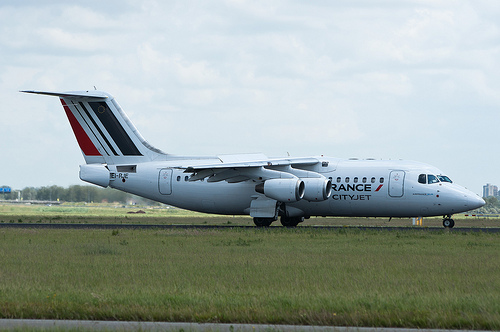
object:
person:
[430, 176, 437, 182]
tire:
[443, 219, 455, 228]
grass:
[0, 202, 500, 324]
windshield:
[436, 175, 452, 183]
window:
[362, 176, 367, 183]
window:
[337, 177, 342, 183]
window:
[344, 177, 349, 184]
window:
[185, 176, 189, 182]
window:
[345, 177, 350, 184]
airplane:
[16, 85, 488, 229]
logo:
[325, 176, 384, 201]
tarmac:
[0, 223, 497, 234]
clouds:
[235, 29, 353, 117]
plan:
[48, 90, 486, 227]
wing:
[168, 157, 321, 183]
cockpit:
[417, 173, 453, 185]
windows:
[176, 175, 182, 181]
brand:
[331, 184, 372, 201]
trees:
[67, 184, 83, 203]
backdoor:
[158, 167, 174, 195]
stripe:
[87, 101, 144, 155]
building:
[483, 183, 498, 198]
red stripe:
[56, 98, 102, 156]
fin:
[58, 90, 158, 163]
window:
[418, 173, 427, 184]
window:
[427, 174, 439, 184]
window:
[436, 175, 452, 183]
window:
[327, 176, 332, 182]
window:
[371, 177, 376, 184]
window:
[379, 177, 385, 183]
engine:
[295, 177, 333, 203]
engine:
[255, 177, 306, 203]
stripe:
[75, 102, 122, 158]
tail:
[17, 89, 164, 159]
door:
[387, 169, 405, 198]